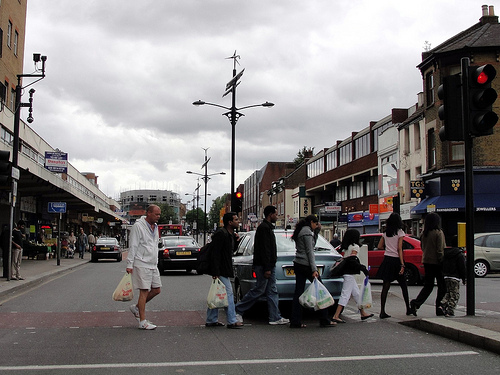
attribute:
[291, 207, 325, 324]
woman — carrying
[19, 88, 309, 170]
cloud — white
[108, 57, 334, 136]
clouds — white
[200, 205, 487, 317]
people — walking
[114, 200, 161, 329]
man — walking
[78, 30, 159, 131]
sky — blue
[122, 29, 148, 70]
clouds — white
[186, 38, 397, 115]
clouds — white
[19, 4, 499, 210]
clouds — white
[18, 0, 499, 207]
sky — blue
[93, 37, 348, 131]
clouds — white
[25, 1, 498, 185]
sky — blue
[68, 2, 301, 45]
cloud — white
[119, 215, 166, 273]
shirt — white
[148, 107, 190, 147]
clouds — white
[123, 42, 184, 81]
sky — blue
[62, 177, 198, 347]
man — wearing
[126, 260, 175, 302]
shorts — white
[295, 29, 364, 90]
clouds — white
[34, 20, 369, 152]
cloud — white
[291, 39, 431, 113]
cloud — white